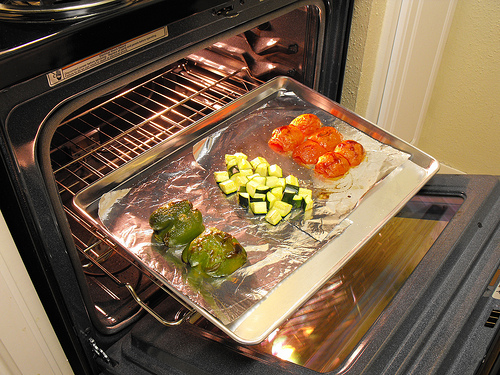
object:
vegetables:
[213, 150, 313, 226]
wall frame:
[367, 0, 457, 146]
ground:
[268, 81, 299, 120]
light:
[188, 38, 280, 76]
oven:
[0, 0, 500, 374]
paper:
[100, 87, 412, 325]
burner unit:
[73, 75, 441, 345]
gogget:
[234, 157, 250, 172]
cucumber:
[212, 151, 316, 225]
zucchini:
[213, 152, 313, 226]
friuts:
[148, 199, 249, 278]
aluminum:
[163, 172, 212, 202]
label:
[45, 25, 169, 89]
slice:
[214, 169, 231, 184]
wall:
[418, 0, 499, 176]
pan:
[268, 113, 368, 178]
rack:
[50, 63, 268, 335]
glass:
[210, 193, 466, 372]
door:
[99, 174, 500, 374]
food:
[150, 113, 368, 278]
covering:
[98, 91, 412, 326]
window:
[49, 7, 321, 325]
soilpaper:
[85, 90, 415, 332]